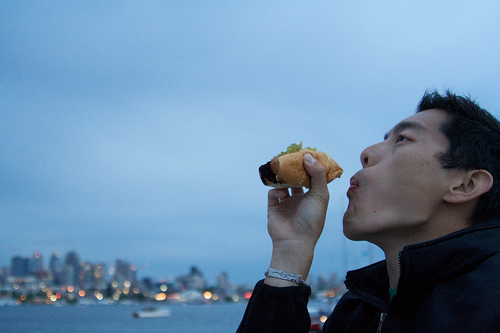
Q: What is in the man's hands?
A: Hotdog.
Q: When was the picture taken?
A: Daytime.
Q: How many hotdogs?
A: 1.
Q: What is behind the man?
A: Water.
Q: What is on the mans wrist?
A: A bracelet.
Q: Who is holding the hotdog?
A: A man.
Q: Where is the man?
A: Beside the water.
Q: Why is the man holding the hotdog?
A: Eating.